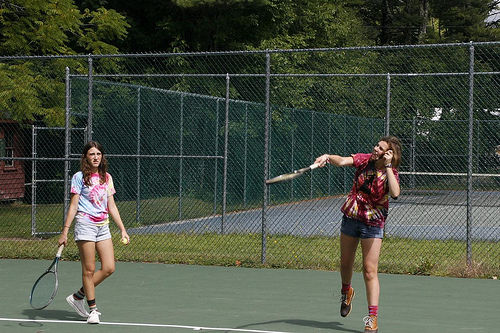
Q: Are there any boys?
A: No, there are no boys.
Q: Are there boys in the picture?
A: No, there are no boys.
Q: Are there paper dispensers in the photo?
A: No, there are no paper dispensers.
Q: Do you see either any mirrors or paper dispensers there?
A: No, there are no paper dispensers or mirrors.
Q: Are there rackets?
A: Yes, there is a racket.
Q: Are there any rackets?
A: Yes, there is a racket.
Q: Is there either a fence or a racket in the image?
A: Yes, there is a racket.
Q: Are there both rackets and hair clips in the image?
A: No, there is a racket but no hair clips.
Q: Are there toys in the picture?
A: No, there are no toys.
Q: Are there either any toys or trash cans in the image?
A: No, there are no toys or trash cans.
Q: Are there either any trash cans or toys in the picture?
A: No, there are no toys or trash cans.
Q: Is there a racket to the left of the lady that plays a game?
A: Yes, there is a racket to the left of the lady.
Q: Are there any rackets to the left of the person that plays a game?
A: Yes, there is a racket to the left of the lady.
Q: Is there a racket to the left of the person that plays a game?
A: Yes, there is a racket to the left of the lady.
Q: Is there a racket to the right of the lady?
A: No, the racket is to the left of the lady.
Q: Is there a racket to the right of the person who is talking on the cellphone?
A: No, the racket is to the left of the lady.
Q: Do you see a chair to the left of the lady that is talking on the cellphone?
A: No, there is a racket to the left of the lady.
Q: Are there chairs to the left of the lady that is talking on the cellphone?
A: No, there is a racket to the left of the lady.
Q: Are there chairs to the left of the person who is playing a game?
A: No, there is a racket to the left of the lady.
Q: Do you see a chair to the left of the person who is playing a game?
A: No, there is a racket to the left of the lady.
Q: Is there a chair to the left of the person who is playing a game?
A: No, there is a racket to the left of the lady.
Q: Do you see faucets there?
A: No, there are no faucets.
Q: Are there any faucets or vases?
A: No, there are no faucets or vases.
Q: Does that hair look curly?
A: Yes, the hair is curly.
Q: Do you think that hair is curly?
A: Yes, the hair is curly.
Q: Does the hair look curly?
A: Yes, the hair is curly.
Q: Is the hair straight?
A: No, the hair is curly.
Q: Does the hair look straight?
A: No, the hair is curly.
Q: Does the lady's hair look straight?
A: No, the hair is curly.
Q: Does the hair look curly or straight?
A: The hair is curly.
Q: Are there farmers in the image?
A: No, there are no farmers.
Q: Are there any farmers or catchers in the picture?
A: No, there are no farmers or catchers.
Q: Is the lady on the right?
A: Yes, the lady is on the right of the image.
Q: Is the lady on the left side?
A: No, the lady is on the right of the image.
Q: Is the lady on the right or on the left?
A: The lady is on the right of the image.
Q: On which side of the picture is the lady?
A: The lady is on the right of the image.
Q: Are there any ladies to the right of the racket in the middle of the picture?
A: Yes, there is a lady to the right of the racket.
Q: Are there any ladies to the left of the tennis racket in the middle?
A: No, the lady is to the right of the tennis racket.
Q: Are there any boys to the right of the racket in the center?
A: No, there is a lady to the right of the tennis racket.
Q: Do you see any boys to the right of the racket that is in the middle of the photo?
A: No, there is a lady to the right of the tennis racket.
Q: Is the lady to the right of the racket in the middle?
A: Yes, the lady is to the right of the tennis racket.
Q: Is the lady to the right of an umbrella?
A: No, the lady is to the right of the tennis racket.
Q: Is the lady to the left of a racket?
A: No, the lady is to the right of a racket.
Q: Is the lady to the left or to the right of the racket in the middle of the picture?
A: The lady is to the right of the tennis racket.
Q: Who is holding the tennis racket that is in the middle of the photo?
A: The lady is holding the racket.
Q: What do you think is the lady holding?
A: The lady is holding the tennis racket.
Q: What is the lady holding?
A: The lady is holding the tennis racket.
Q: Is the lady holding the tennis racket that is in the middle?
A: Yes, the lady is holding the tennis racket.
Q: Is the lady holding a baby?
A: No, the lady is holding the tennis racket.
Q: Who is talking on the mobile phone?
A: The lady is talking on the mobile phone.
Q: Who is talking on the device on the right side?
A: The lady is talking on the mobile phone.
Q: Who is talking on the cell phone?
A: The lady is talking on the mobile phone.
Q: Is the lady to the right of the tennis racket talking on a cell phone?
A: Yes, the lady is talking on a cell phone.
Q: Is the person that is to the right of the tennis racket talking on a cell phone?
A: Yes, the lady is talking on a cell phone.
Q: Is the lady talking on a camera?
A: No, the lady is talking on a cell phone.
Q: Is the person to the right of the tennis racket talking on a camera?
A: No, the lady is talking on a cell phone.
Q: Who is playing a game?
A: The lady is playing a game.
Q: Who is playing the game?
A: The lady is playing a game.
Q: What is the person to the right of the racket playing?
A: The lady is playing a game.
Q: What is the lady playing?
A: The lady is playing a game.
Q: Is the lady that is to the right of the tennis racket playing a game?
A: Yes, the lady is playing a game.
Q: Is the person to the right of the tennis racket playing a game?
A: Yes, the lady is playing a game.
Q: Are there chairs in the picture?
A: No, there are no chairs.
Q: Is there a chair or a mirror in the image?
A: No, there are no chairs or mirrors.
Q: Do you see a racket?
A: Yes, there is a racket.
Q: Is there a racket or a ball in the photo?
A: Yes, there is a racket.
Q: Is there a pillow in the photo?
A: No, there are no pillows.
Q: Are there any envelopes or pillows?
A: No, there are no pillows or envelopes.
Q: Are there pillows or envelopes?
A: No, there are no pillows or envelopes.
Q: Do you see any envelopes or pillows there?
A: No, there are no pillows or envelopes.